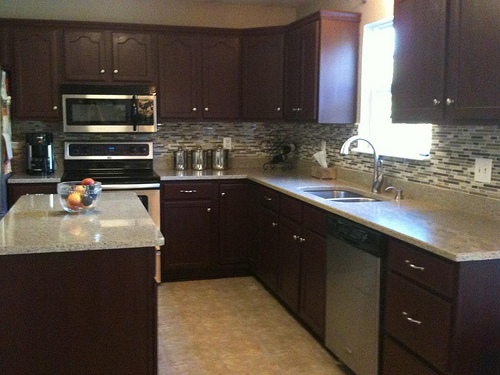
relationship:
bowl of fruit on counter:
[60, 181, 95, 205] [4, 193, 167, 247]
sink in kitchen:
[309, 186, 365, 205] [2, 7, 500, 374]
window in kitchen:
[363, 25, 432, 150] [2, 7, 500, 374]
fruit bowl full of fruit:
[55, 178, 104, 215] [76, 180, 100, 187]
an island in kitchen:
[8, 195, 162, 373] [2, 7, 500, 374]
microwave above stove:
[62, 95, 161, 129] [65, 144, 160, 219]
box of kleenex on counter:
[311, 145, 333, 173] [239, 160, 345, 188]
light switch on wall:
[470, 155, 493, 185] [297, 100, 499, 197]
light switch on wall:
[473, 155, 491, 181] [297, 100, 499, 197]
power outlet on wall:
[223, 139, 233, 148] [10, 129, 316, 167]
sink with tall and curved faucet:
[309, 186, 365, 205] [335, 135, 386, 189]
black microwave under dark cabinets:
[62, 95, 161, 129] [3, 28, 353, 117]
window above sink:
[363, 25, 432, 150] [309, 186, 365, 205]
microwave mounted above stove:
[62, 95, 161, 129] [65, 144, 160, 219]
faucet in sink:
[335, 135, 386, 189] [309, 186, 365, 205]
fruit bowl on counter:
[60, 181, 95, 205] [4, 193, 167, 247]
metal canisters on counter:
[177, 146, 230, 169] [239, 160, 345, 188]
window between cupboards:
[363, 25, 432, 150] [241, 19, 496, 124]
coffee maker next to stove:
[26, 132, 51, 170] [65, 144, 160, 219]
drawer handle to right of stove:
[179, 188, 199, 191] [65, 144, 160, 219]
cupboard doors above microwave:
[61, 30, 158, 86] [62, 95, 161, 129]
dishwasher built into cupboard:
[318, 228, 386, 369] [256, 200, 459, 353]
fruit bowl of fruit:
[55, 178, 104, 215] [76, 180, 100, 187]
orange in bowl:
[68, 191, 80, 203] [60, 181, 95, 205]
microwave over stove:
[62, 95, 161, 129] [65, 144, 160, 219]